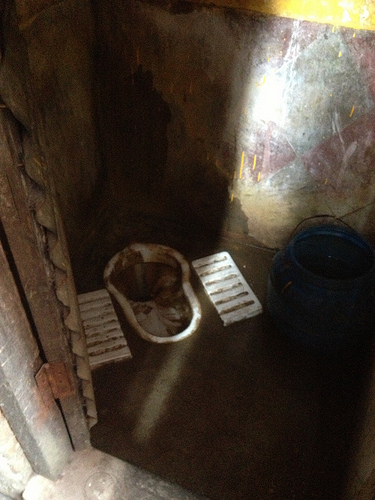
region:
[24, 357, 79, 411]
hinge on a door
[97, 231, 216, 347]
hole in the ground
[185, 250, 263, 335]
vent on the ground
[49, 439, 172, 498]
sill of a window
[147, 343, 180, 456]
light casted on the ground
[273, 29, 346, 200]
light casted on the wall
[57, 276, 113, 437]
shingles on a door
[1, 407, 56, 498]
rocks on a wall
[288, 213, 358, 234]
handle on a jar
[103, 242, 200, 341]
commode in the floor of an out house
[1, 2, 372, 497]
an old outhouse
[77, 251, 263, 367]
two white plastic rectangles to stand on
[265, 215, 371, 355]
a blue pot on the ground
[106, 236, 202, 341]
nasty white porcelain toilet in the ground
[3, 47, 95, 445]
outhouse door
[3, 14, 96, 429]
metal sheeting on the door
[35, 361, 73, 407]
a rusty door hinge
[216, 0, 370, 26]
a yellow line on the all of the outhouse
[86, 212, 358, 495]
the dirt floor of the outhouse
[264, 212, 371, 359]
the bucket is blue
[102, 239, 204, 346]
hole in the ground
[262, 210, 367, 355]
blue bucket on the ground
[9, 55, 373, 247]
paint chipping off wall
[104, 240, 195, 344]
the hole is dirty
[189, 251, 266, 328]
white part on the floor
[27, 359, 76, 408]
metal piece on door frame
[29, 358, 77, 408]
door hinge is rusty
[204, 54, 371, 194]
light shining on wall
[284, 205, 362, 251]
handle on the bucket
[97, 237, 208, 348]
A hole in the ground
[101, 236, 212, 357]
A white hole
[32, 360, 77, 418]
A hinge on a doorframe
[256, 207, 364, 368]
A blue pot on the ground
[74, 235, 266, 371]
A toilet on the floor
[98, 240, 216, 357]
A dirty white toilet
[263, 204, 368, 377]
A dark blue pot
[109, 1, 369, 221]
Yellow paint splattered on wall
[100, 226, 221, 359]
A hole in the floor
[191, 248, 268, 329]
A white piece of plastic on the floor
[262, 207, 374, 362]
The pottery vase on the floor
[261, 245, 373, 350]
The vase is the color blue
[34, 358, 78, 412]
The hinge on the door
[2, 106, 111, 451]
The door to the room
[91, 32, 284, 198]
The wall is made of concrete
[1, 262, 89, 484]
The door way is made of concrete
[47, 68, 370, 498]
The room is very small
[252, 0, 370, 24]
The color on the wall is yellow